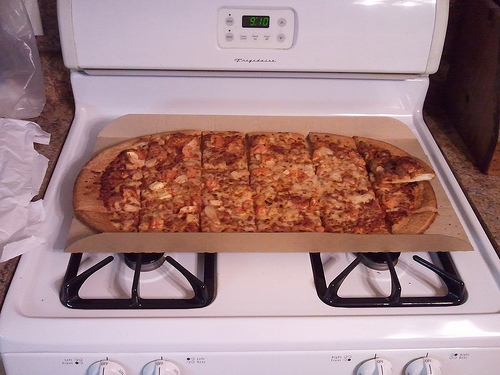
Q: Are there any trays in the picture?
A: No, there are no trays.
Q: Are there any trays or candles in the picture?
A: No, there are no trays or candles.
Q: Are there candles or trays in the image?
A: No, there are no trays or candles.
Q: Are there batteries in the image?
A: No, there are no batteries.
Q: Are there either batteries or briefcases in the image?
A: No, there are no batteries or briefcases.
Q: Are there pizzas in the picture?
A: Yes, there is a pizza.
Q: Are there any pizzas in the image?
A: Yes, there is a pizza.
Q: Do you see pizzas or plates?
A: Yes, there is a pizza.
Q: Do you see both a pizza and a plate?
A: No, there is a pizza but no plates.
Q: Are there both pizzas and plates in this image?
A: No, there is a pizza but no plates.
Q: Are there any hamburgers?
A: No, there are no hamburgers.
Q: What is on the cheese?
A: The pizza is on the cheese.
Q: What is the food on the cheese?
A: The food is a pizza.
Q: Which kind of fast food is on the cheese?
A: The food is a pizza.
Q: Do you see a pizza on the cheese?
A: Yes, there is a pizza on the cheese.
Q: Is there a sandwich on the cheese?
A: No, there is a pizza on the cheese.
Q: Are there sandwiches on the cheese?
A: No, there is a pizza on the cheese.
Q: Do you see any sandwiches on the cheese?
A: No, there is a pizza on the cheese.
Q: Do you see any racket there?
A: No, there are no rackets.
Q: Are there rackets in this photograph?
A: No, there are no rackets.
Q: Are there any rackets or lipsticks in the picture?
A: No, there are no rackets or lipsticks.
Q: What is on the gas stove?
A: The stove top is on the gas stove.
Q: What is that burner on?
A: The burner is on the gas stove.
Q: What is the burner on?
A: The burner is on the gas stove.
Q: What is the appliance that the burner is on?
A: The appliance is a gas stove.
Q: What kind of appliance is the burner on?
A: The burner is on the gas stove.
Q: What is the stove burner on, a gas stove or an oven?
A: The stove burner is on a gas stove.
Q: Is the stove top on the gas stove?
A: Yes, the stove top is on the gas stove.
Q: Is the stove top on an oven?
A: No, the stove top is on the gas stove.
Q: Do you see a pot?
A: No, there are no pots.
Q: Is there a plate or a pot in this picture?
A: No, there are no pots or plates.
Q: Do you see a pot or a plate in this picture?
A: No, there are no pots or plates.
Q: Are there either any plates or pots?
A: No, there are no pots or plates.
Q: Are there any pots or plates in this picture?
A: No, there are no pots or plates.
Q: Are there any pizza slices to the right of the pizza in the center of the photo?
A: Yes, there is a pizza slice to the right of the pizza.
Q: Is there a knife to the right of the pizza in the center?
A: No, there is a pizza slice to the right of the pizza.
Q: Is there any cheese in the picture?
A: Yes, there is cheese.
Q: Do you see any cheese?
A: Yes, there is cheese.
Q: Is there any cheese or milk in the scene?
A: Yes, there is cheese.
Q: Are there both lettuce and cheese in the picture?
A: No, there is cheese but no lettuce.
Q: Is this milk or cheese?
A: This is cheese.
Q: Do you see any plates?
A: No, there are no plates.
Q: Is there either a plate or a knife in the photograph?
A: No, there are no plates or knives.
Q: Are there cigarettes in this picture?
A: No, there are no cigarettes.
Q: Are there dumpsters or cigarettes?
A: No, there are no cigarettes or dumpsters.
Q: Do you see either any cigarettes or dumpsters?
A: No, there are no cigarettes or dumpsters.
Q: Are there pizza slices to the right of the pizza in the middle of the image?
A: Yes, there is a pizza slice to the right of the pizza.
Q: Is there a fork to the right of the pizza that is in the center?
A: No, there is a pizza slice to the right of the pizza.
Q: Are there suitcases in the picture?
A: No, there are no suitcases.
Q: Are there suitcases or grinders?
A: No, there are no suitcases or grinders.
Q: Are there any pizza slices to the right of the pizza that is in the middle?
A: Yes, there is a pizza slice to the right of the pizza.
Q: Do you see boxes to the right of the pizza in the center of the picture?
A: No, there is a pizza slice to the right of the pizza.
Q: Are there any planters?
A: No, there are no planters.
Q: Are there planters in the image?
A: No, there are no planters.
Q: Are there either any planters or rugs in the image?
A: No, there are no planters or rugs.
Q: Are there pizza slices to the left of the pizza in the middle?
A: Yes, there is a pizza slice to the left of the pizza.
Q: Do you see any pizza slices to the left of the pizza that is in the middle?
A: Yes, there is a pizza slice to the left of the pizza.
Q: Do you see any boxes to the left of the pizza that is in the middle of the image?
A: No, there is a pizza slice to the left of the pizza.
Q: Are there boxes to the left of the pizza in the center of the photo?
A: No, there is a pizza slice to the left of the pizza.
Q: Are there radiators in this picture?
A: No, there are no radiators.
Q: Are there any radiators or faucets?
A: No, there are no radiators or faucets.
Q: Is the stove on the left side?
A: Yes, the stove is on the left of the image.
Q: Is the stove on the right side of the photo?
A: No, the stove is on the left of the image.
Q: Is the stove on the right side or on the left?
A: The stove is on the left of the image.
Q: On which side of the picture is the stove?
A: The stove is on the left of the image.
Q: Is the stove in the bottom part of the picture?
A: Yes, the stove is in the bottom of the image.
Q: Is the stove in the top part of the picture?
A: No, the stove is in the bottom of the image.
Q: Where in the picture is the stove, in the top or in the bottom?
A: The stove is in the bottom of the image.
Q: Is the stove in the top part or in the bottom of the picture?
A: The stove is in the bottom of the image.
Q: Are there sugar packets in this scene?
A: No, there are no sugar packets.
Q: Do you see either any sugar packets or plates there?
A: No, there are no sugar packets or plates.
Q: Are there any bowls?
A: No, there are no bowls.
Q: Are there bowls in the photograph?
A: No, there are no bowls.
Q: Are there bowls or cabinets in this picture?
A: No, there are no bowls or cabinets.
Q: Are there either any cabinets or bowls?
A: No, there are no bowls or cabinets.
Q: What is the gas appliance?
A: The appliance is a gas stove.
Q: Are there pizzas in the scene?
A: Yes, there is a pizza.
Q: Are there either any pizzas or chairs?
A: Yes, there is a pizza.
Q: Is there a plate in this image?
A: No, there are no plates.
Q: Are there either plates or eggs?
A: No, there are no plates or eggs.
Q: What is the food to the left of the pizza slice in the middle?
A: The food is a pizza.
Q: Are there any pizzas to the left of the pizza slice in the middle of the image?
A: Yes, there is a pizza to the left of the pizza slice.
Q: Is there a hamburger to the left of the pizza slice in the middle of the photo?
A: No, there is a pizza to the left of the pizza slice.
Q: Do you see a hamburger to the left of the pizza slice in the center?
A: No, there is a pizza to the left of the pizza slice.